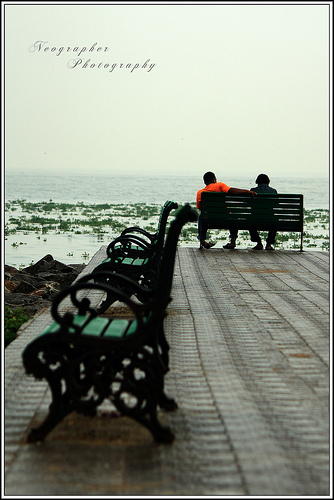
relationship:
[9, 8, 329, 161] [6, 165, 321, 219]
sky over ocean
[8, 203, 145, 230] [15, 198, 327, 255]
grass patches on beach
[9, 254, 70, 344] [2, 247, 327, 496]
rocks near boardwalk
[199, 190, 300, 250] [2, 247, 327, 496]
bench on boardwalk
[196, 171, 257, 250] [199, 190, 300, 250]
man sitting on bench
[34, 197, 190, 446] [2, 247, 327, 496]
benches on boardwalk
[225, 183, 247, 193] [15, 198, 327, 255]
man's arm on beach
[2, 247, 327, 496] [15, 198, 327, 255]
boardwalk on beach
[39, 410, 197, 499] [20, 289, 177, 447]
shadow of bench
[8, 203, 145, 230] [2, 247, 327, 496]
grass patches near boardwalk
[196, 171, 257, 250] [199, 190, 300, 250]
man on bench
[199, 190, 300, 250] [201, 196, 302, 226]
bench has back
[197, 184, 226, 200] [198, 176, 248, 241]
orange shirt on man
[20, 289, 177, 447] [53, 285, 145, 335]
bench has curved arm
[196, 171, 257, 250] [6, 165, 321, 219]
man facing ocean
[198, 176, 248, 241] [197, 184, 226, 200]
man has orange shirt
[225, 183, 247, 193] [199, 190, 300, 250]
man's arm on bench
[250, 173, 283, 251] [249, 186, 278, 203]
woman wearing gray top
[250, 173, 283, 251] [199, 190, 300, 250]
woman on bench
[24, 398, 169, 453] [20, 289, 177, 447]
cement holds bench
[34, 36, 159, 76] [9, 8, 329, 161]
copyright under sky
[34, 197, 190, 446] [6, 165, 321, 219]
benches near ocean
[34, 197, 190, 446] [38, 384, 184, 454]
benches have legs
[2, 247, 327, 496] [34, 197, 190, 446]
boardwalk under benches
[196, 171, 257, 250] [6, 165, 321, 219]
man near ocean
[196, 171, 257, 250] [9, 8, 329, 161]
man under sky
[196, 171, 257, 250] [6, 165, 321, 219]
man watching ocean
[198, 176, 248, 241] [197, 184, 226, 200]
man wearing orange shirt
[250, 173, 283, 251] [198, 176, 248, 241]
woman by man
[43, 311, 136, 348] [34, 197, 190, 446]
seat on benches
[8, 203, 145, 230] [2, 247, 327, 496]
grass patches in front of boardwalk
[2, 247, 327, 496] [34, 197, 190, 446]
boardwalk with benches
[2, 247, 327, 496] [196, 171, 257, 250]
boardwalk with man